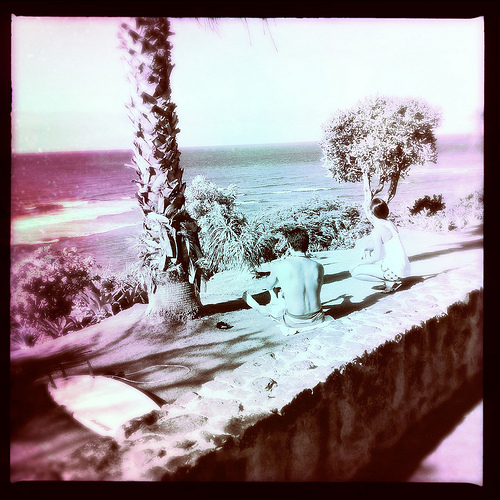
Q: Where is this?
A: This is at the beach.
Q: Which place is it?
A: It is a beach.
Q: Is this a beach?
A: Yes, it is a beach.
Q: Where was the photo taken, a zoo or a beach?
A: It was taken at a beach.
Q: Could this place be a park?
A: No, it is a beach.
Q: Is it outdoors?
A: Yes, it is outdoors.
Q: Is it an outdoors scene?
A: Yes, it is outdoors.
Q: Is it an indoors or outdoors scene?
A: It is outdoors.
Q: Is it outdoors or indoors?
A: It is outdoors.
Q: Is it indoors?
A: No, it is outdoors.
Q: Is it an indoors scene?
A: No, it is outdoors.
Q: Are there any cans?
A: No, there are no cans.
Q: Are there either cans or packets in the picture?
A: No, there are no cans or packets.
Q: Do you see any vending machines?
A: No, there are no vending machines.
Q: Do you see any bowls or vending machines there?
A: No, there are no vending machines or bowls.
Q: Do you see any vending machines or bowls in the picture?
A: No, there are no vending machines or bowls.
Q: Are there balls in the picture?
A: No, there are no balls.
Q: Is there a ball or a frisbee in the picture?
A: No, there are no balls or frisbees.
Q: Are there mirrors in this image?
A: No, there are no mirrors.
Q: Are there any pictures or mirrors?
A: No, there are no mirrors or pictures.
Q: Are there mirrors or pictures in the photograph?
A: No, there are no mirrors or pictures.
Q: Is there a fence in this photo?
A: No, there are no fences.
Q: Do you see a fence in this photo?
A: No, there are no fences.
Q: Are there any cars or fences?
A: No, there are no fences or cars.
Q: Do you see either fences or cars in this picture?
A: No, there are no fences or cars.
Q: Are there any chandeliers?
A: No, there are no chandeliers.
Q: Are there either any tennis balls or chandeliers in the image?
A: No, there are no chandeliers or tennis balls.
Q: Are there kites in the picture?
A: No, there are no kites.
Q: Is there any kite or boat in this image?
A: No, there are no kites or boats.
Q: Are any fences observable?
A: No, there are no fences.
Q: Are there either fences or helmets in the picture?
A: No, there are no fences or helmets.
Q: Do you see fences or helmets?
A: No, there are no fences or helmets.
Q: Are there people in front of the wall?
A: Yes, there is a person in front of the wall.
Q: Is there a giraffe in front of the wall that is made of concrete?
A: No, there is a person in front of the wall.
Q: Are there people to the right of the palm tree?
A: Yes, there is a person to the right of the palm tree.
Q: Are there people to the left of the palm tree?
A: No, the person is to the right of the palm tree.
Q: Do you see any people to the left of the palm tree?
A: No, the person is to the right of the palm tree.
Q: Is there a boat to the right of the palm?
A: No, there is a person to the right of the palm.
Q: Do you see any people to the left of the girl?
A: Yes, there is a person to the left of the girl.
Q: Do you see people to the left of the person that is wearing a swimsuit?
A: Yes, there is a person to the left of the girl.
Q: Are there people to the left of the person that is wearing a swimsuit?
A: Yes, there is a person to the left of the girl.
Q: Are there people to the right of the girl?
A: No, the person is to the left of the girl.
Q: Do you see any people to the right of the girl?
A: No, the person is to the left of the girl.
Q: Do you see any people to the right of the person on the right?
A: No, the person is to the left of the girl.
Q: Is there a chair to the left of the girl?
A: No, there is a person to the left of the girl.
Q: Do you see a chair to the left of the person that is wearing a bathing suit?
A: No, there is a person to the left of the girl.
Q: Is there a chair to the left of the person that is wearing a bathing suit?
A: No, there is a person to the left of the girl.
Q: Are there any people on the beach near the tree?
A: Yes, there is a person on the beach.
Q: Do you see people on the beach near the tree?
A: Yes, there is a person on the beach.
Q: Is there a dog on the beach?
A: No, there is a person on the beach.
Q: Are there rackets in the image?
A: No, there are no rackets.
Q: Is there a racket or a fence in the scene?
A: No, there are no rackets or fences.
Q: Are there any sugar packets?
A: No, there are no sugar packets.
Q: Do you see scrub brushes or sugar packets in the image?
A: No, there are no sugar packets or scrub brushes.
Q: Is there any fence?
A: No, there are no fences.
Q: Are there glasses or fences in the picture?
A: No, there are no fences or glasses.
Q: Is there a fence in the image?
A: No, there are no fences.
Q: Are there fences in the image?
A: No, there are no fences.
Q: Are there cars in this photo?
A: No, there are no cars.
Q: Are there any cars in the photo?
A: No, there are no cars.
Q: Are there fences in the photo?
A: No, there are no fences.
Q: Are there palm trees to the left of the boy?
A: Yes, there is a palm tree to the left of the boy.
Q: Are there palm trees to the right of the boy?
A: No, the palm tree is to the left of the boy.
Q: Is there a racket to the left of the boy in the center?
A: No, there is a palm tree to the left of the boy.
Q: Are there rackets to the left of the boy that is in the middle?
A: No, there is a palm tree to the left of the boy.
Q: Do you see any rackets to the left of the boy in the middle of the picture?
A: No, there is a palm tree to the left of the boy.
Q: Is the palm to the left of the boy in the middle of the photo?
A: Yes, the palm is to the left of the boy.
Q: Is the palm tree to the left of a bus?
A: No, the palm tree is to the left of the boy.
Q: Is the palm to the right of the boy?
A: No, the palm is to the left of the boy.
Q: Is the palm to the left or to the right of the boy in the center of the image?
A: The palm is to the left of the boy.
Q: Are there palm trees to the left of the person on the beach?
A: Yes, there is a palm tree to the left of the person.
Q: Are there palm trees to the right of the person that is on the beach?
A: No, the palm tree is to the left of the person.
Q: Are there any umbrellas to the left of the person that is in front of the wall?
A: No, there is a palm tree to the left of the person.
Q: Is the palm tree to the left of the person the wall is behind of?
A: Yes, the palm tree is to the left of the person.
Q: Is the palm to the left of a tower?
A: No, the palm is to the left of the person.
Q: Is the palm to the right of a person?
A: No, the palm is to the left of a person.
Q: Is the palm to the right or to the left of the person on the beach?
A: The palm is to the left of the person.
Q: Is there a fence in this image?
A: No, there are no fences.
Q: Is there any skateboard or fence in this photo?
A: No, there are no fences or skateboards.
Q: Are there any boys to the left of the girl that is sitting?
A: Yes, there is a boy to the left of the girl.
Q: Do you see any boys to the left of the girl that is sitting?
A: Yes, there is a boy to the left of the girl.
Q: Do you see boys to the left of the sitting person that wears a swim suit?
A: Yes, there is a boy to the left of the girl.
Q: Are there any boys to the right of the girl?
A: No, the boy is to the left of the girl.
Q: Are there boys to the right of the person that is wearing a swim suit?
A: No, the boy is to the left of the girl.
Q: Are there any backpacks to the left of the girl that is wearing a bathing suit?
A: No, there is a boy to the left of the girl.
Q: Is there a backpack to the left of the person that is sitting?
A: No, there is a boy to the left of the girl.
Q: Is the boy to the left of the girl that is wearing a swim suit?
A: Yes, the boy is to the left of the girl.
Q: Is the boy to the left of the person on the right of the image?
A: Yes, the boy is to the left of the girl.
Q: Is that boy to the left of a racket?
A: No, the boy is to the left of the girl.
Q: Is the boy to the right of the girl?
A: No, the boy is to the left of the girl.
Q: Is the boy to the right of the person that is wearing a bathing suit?
A: No, the boy is to the left of the girl.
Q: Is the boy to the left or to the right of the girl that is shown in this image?
A: The boy is to the left of the girl.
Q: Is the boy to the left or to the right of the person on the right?
A: The boy is to the left of the girl.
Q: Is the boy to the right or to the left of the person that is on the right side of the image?
A: The boy is to the left of the girl.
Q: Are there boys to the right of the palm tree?
A: Yes, there is a boy to the right of the palm tree.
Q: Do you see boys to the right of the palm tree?
A: Yes, there is a boy to the right of the palm tree.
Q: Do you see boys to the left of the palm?
A: No, the boy is to the right of the palm.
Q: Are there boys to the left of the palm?
A: No, the boy is to the right of the palm.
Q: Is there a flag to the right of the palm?
A: No, there is a boy to the right of the palm.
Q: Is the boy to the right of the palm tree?
A: Yes, the boy is to the right of the palm tree.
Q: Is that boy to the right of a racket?
A: No, the boy is to the right of the palm tree.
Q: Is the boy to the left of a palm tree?
A: No, the boy is to the right of a palm tree.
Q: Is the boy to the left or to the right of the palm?
A: The boy is to the right of the palm.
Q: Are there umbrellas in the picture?
A: No, there are no umbrellas.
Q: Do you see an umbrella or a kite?
A: No, there are no umbrellas or kites.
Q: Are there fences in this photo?
A: No, there are no fences.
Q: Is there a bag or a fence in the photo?
A: No, there are no fences or bags.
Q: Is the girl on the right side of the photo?
A: Yes, the girl is on the right of the image.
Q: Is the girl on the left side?
A: No, the girl is on the right of the image.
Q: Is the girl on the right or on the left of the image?
A: The girl is on the right of the image.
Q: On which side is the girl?
A: The girl is on the right of the image.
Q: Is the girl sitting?
A: Yes, the girl is sitting.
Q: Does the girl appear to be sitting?
A: Yes, the girl is sitting.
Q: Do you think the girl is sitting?
A: Yes, the girl is sitting.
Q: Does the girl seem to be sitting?
A: Yes, the girl is sitting.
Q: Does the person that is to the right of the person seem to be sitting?
A: Yes, the girl is sitting.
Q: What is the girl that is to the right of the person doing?
A: The girl is sitting.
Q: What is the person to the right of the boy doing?
A: The girl is sitting.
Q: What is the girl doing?
A: The girl is sitting.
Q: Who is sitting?
A: The girl is sitting.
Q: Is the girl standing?
A: No, the girl is sitting.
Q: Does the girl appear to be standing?
A: No, the girl is sitting.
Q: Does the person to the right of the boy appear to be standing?
A: No, the girl is sitting.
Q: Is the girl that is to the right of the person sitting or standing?
A: The girl is sitting.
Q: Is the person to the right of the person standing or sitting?
A: The girl is sitting.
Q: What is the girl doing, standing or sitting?
A: The girl is sitting.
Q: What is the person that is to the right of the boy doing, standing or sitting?
A: The girl is sitting.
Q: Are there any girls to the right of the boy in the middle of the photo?
A: Yes, there is a girl to the right of the boy.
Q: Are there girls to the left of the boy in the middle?
A: No, the girl is to the right of the boy.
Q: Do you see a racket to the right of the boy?
A: No, there is a girl to the right of the boy.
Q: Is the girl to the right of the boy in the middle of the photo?
A: Yes, the girl is to the right of the boy.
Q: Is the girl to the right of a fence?
A: No, the girl is to the right of the boy.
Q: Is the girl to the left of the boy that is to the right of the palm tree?
A: No, the girl is to the right of the boy.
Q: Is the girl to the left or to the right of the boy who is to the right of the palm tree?
A: The girl is to the right of the boy.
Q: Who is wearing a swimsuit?
A: The girl is wearing a swimsuit.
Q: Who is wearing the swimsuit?
A: The girl is wearing a swimsuit.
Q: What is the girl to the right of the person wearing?
A: The girl is wearing a swimsuit.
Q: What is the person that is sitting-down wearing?
A: The girl is wearing a swimsuit.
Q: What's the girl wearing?
A: The girl is wearing a swimsuit.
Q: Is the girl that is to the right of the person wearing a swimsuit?
A: Yes, the girl is wearing a swimsuit.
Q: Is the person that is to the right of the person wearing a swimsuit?
A: Yes, the girl is wearing a swimsuit.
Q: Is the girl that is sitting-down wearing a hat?
A: No, the girl is wearing a swimsuit.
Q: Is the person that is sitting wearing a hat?
A: No, the girl is wearing a swimsuit.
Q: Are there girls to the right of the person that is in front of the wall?
A: Yes, there is a girl to the right of the person.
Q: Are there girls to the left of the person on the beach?
A: No, the girl is to the right of the person.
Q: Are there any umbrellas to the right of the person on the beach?
A: No, there is a girl to the right of the person.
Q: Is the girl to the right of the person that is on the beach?
A: Yes, the girl is to the right of the person.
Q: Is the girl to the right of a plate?
A: No, the girl is to the right of the person.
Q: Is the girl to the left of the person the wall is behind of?
A: No, the girl is to the right of the person.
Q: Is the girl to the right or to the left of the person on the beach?
A: The girl is to the right of the person.